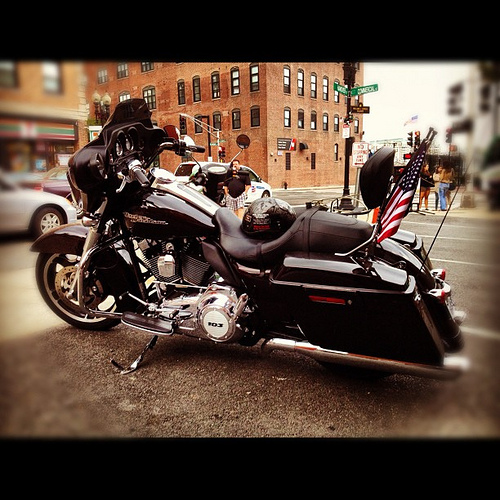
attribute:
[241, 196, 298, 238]
helmet — black, gold, white,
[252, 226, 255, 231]
letter — red 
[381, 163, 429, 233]
flag — american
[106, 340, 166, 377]
stand — kick stand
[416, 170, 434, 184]
shirt — black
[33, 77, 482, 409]
motorcycle — parked, black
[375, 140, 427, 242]
flag — american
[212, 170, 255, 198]
shirt — black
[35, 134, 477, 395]
motorcycle — parked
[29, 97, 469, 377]
motorcycle — black, parked